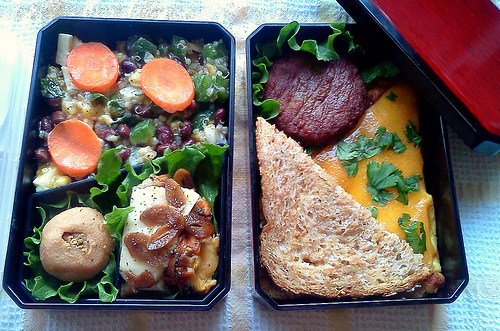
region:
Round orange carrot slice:
[137, 55, 193, 121]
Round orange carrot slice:
[64, 43, 117, 88]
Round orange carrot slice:
[45, 120, 100, 173]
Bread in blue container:
[252, 115, 432, 295]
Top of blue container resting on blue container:
[337, 0, 498, 160]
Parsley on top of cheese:
[397, 207, 428, 256]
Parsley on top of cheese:
[365, 157, 395, 193]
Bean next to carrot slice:
[119, 55, 134, 69]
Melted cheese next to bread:
[303, 88, 438, 265]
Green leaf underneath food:
[15, 188, 125, 300]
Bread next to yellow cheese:
[255, 113, 425, 293]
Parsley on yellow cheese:
[399, 211, 427, 255]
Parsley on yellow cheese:
[359, 156, 399, 199]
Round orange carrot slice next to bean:
[66, 40, 119, 90]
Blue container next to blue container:
[5, 16, 239, 308]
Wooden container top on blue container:
[330, 0, 497, 155]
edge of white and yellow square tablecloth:
[203, 310, 270, 325]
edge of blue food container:
[11, 288, 230, 315]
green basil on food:
[336, 140, 404, 183]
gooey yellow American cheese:
[336, 173, 370, 190]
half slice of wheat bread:
[250, 112, 429, 286]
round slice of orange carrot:
[135, 45, 197, 111]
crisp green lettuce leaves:
[97, 148, 161, 190]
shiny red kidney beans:
[103, 122, 132, 141]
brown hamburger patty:
[262, 49, 364, 134]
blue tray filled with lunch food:
[19, 21, 250, 257]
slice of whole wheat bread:
[256, 113, 433, 295]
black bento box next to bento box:
[7, 13, 242, 314]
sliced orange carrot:
[138, 58, 193, 106]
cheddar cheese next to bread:
[311, 88, 440, 265]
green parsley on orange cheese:
[368, 160, 403, 194]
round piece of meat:
[267, 51, 363, 139]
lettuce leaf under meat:
[256, 23, 369, 124]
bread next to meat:
[257, 117, 436, 297]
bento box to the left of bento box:
[3, 14, 235, 310]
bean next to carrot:
[116, 123, 130, 137]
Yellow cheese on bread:
[321, 74, 440, 275]